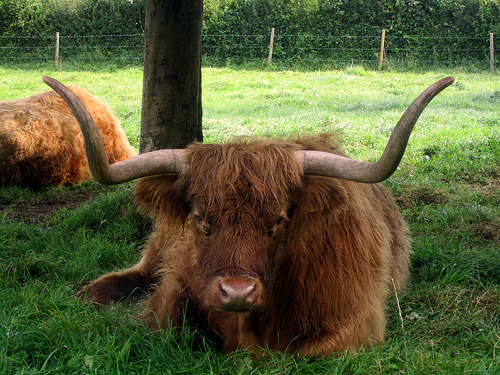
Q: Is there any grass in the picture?
A: Yes, there is grass.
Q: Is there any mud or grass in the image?
A: Yes, there is grass.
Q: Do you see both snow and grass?
A: No, there is grass but no snow.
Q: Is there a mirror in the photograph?
A: No, there are no mirrors.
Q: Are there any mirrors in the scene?
A: No, there are no mirrors.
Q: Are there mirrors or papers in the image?
A: No, there are no mirrors or papers.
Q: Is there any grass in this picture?
A: Yes, there is grass.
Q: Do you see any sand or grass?
A: Yes, there is grass.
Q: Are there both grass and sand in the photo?
A: No, there is grass but no sand.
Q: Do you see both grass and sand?
A: No, there is grass but no sand.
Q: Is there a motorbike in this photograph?
A: No, there are no motorcycles.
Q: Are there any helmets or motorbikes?
A: No, there are no motorbikes or helmets.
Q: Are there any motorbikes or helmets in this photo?
A: No, there are no motorbikes or helmets.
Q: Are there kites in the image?
A: No, there are no kites.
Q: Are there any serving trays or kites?
A: No, there are no kites or serving trays.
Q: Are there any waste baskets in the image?
A: No, there are no waste baskets.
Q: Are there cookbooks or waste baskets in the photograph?
A: No, there are no waste baskets or cookbooks.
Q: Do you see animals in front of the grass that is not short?
A: Yes, there is an animal in front of the grass.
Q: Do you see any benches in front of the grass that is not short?
A: No, there is an animal in front of the grass.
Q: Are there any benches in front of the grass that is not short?
A: No, there is an animal in front of the grass.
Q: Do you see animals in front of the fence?
A: Yes, there is an animal in front of the fence.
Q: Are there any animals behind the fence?
A: No, the animal is in front of the fence.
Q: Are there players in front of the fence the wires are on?
A: No, there is an animal in front of the fence.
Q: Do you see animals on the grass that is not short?
A: Yes, there is an animal on the grass.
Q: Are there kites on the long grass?
A: No, there is an animal on the grass.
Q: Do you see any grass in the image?
A: Yes, there is grass.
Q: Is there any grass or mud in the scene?
A: Yes, there is grass.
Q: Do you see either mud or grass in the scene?
A: Yes, there is grass.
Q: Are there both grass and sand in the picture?
A: No, there is grass but no sand.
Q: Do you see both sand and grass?
A: No, there is grass but no sand.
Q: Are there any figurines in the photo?
A: No, there are no figurines.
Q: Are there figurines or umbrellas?
A: No, there are no figurines or umbrellas.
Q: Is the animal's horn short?
A: No, the horn is long.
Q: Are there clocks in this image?
A: No, there are no clocks.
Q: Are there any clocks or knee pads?
A: No, there are no clocks or knee pads.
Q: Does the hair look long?
A: Yes, the hair is long.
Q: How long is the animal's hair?
A: The hair is long.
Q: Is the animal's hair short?
A: No, the hair is long.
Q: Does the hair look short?
A: No, the hair is long.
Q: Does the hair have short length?
A: No, the hair is long.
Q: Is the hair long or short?
A: The hair is long.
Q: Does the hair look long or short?
A: The hair is long.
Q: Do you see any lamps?
A: No, there are no lamps.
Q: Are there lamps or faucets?
A: No, there are no lamps or faucets.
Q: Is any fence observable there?
A: Yes, there is a fence.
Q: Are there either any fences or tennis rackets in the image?
A: Yes, there is a fence.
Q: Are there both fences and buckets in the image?
A: No, there is a fence but no buckets.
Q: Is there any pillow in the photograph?
A: No, there are no pillows.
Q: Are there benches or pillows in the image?
A: No, there are no pillows or benches.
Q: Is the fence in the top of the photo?
A: Yes, the fence is in the top of the image.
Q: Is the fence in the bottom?
A: No, the fence is in the top of the image.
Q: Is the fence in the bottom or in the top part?
A: The fence is in the top of the image.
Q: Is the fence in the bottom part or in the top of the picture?
A: The fence is in the top of the image.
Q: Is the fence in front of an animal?
A: No, the fence is behind an animal.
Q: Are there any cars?
A: No, there are no cars.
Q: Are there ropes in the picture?
A: No, there are no ropes.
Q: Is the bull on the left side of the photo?
A: Yes, the bull is on the left of the image.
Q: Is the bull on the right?
A: No, the bull is on the left of the image.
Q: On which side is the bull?
A: The bull is on the left of the image.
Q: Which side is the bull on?
A: The bull is on the left of the image.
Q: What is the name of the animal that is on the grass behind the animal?
A: The animal is a bull.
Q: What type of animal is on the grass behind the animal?
A: The animal is a bull.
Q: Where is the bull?
A: The bull is on the grass.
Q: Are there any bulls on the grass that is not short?
A: Yes, there is a bull on the grass.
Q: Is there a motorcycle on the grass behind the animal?
A: No, there is a bull on the grass.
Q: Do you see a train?
A: No, there are no trains.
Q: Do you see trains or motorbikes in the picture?
A: No, there are no trains or motorbikes.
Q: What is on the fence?
A: The wires are on the fence.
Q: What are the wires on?
A: The wires are on the fence.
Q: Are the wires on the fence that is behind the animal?
A: Yes, the wires are on the fence.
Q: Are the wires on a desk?
A: No, the wires are on the fence.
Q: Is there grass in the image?
A: Yes, there is grass.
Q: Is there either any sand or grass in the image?
A: Yes, there is grass.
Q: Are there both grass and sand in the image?
A: No, there is grass but no sand.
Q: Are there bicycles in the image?
A: No, there are no bicycles.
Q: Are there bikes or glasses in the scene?
A: No, there are no bikes or glasses.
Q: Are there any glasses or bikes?
A: No, there are no bikes or glasses.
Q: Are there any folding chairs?
A: No, there are no folding chairs.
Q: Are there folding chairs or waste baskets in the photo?
A: No, there are no folding chairs or waste baskets.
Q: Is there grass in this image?
A: Yes, there is grass.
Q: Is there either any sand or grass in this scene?
A: Yes, there is grass.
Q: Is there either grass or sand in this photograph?
A: Yes, there is grass.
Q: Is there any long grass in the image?
A: Yes, there is long grass.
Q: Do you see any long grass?
A: Yes, there is long grass.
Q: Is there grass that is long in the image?
A: Yes, there is long grass.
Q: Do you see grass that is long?
A: Yes, there is grass that is long.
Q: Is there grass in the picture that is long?
A: Yes, there is grass that is long.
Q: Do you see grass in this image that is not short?
A: Yes, there is long grass.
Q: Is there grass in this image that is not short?
A: Yes, there is long grass.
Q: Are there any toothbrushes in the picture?
A: No, there are no toothbrushes.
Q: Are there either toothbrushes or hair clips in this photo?
A: No, there are no toothbrushes or hair clips.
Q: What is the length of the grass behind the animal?
A: The grass is long.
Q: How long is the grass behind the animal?
A: The grass is long.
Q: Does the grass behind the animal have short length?
A: No, the grass is long.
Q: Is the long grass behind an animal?
A: Yes, the grass is behind an animal.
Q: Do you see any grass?
A: Yes, there is grass.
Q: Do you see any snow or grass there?
A: Yes, there is grass.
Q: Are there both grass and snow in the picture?
A: No, there is grass but no snow.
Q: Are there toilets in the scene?
A: No, there are no toilets.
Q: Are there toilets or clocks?
A: No, there are no toilets or clocks.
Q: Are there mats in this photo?
A: No, there are no mats.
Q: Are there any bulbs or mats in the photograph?
A: No, there are no mats or bulbs.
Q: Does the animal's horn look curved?
A: Yes, the horn is curved.